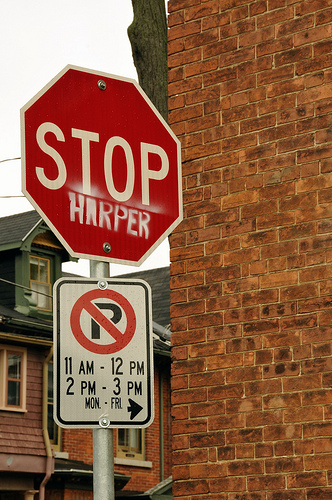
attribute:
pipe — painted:
[88, 258, 115, 498]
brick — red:
[254, 62, 296, 84]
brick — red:
[255, 121, 295, 143]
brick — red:
[277, 193, 319, 211]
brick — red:
[235, 224, 282, 247]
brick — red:
[279, 282, 318, 299]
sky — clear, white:
[33, 8, 108, 47]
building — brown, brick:
[163, 1, 329, 497]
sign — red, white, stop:
[15, 59, 187, 266]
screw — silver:
[99, 417, 109, 426]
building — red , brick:
[113, 54, 328, 494]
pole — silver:
[89, 259, 114, 499]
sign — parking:
[52, 277, 153, 429]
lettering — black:
[81, 394, 124, 411]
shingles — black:
[4, 217, 31, 234]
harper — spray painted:
[63, 186, 157, 240]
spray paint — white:
[63, 185, 154, 242]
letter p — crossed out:
[67, 286, 137, 354]